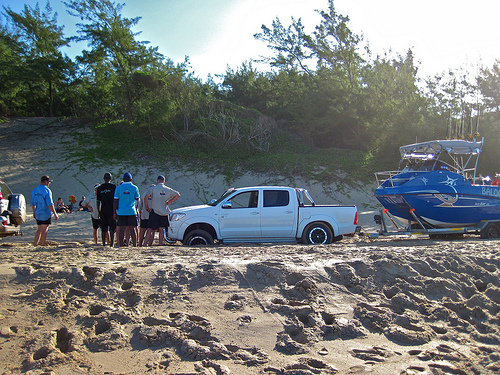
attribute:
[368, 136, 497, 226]
boat — blue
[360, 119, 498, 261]
boat —  blue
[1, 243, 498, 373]
beach hill — sandy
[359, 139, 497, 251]
boat — blue, white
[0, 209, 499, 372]
sand — tan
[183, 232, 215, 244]
tire —  spare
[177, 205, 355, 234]
truck — white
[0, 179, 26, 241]
car —  the back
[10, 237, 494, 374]
sandy area —  flat ,  sandy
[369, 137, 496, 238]
boat — blue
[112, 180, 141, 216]
blue shirt —  light blue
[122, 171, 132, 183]
baseball cap — of baseball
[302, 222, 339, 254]
tire — back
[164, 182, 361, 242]
truck — pick up, white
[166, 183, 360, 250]
white truck —  white,  dual cab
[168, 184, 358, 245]
pickup truck — white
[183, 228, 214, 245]
tire —  the front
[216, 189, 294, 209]
window — down